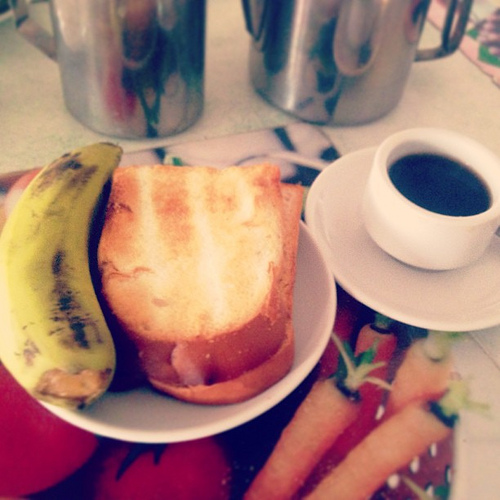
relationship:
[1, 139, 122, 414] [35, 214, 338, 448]
banana on bowl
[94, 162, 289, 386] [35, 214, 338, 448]
toast on bowl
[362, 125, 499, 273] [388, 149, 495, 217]
cup of coffee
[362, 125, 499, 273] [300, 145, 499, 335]
cup on saucer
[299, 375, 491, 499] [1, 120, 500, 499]
carrot on mat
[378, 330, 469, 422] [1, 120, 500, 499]
carrot on mat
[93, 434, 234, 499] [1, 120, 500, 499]
tomato on mat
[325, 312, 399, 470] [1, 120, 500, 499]
carrot on mat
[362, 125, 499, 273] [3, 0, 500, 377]
cup on table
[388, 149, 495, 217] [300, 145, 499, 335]
coffee on saucer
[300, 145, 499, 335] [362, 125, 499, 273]
saucer under cup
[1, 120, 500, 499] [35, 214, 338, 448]
mat under bowl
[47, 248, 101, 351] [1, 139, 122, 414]
spot on banana